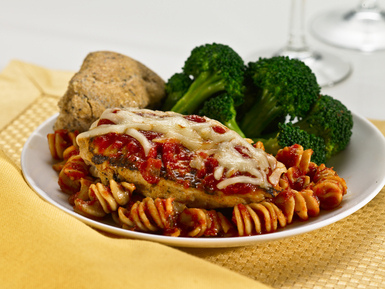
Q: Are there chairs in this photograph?
A: No, there are no chairs.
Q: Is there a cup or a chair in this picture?
A: No, there are no chairs or cups.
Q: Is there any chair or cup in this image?
A: No, there are no chairs or cups.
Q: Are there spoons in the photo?
A: No, there are no spoons.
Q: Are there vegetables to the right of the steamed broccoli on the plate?
A: Yes, there is a vegetable to the right of the broccoli.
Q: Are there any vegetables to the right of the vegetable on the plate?
A: Yes, there is a vegetable to the right of the broccoli.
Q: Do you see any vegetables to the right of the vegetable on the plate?
A: Yes, there is a vegetable to the right of the broccoli.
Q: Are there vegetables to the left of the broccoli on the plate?
A: No, the vegetable is to the right of the broccoli.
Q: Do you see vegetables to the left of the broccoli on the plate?
A: No, the vegetable is to the right of the broccoli.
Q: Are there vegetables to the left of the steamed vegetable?
A: No, the vegetable is to the right of the broccoli.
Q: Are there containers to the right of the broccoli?
A: No, there is a vegetable to the right of the broccoli.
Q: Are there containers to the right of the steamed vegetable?
A: No, there is a vegetable to the right of the broccoli.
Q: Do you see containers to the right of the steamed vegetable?
A: No, there is a vegetable to the right of the broccoli.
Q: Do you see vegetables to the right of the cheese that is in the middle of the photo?
A: Yes, there is a vegetable to the right of the cheese.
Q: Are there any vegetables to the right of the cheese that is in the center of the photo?
A: Yes, there is a vegetable to the right of the cheese.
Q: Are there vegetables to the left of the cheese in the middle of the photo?
A: No, the vegetable is to the right of the cheese.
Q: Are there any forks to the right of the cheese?
A: No, there is a vegetable to the right of the cheese.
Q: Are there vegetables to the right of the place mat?
A: Yes, there is a vegetable to the right of the place mat.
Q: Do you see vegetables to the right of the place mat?
A: Yes, there is a vegetable to the right of the place mat.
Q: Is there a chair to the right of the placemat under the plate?
A: No, there is a vegetable to the right of the placemat.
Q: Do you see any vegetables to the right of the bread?
A: Yes, there is a vegetable to the right of the bread.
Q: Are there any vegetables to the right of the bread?
A: Yes, there is a vegetable to the right of the bread.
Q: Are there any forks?
A: No, there are no forks.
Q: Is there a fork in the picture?
A: No, there are no forks.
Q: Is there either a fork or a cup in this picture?
A: No, there are no forks or cups.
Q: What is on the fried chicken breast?
A: The sauce is on the chicken breast.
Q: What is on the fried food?
A: The sauce is on the chicken breast.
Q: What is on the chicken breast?
A: The sauce is on the chicken breast.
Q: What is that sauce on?
A: The sauce is on the chicken breast.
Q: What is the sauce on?
A: The sauce is on the chicken breast.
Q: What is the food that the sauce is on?
A: The food is chicken breast.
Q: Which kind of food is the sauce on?
A: The sauce is on the chicken breast.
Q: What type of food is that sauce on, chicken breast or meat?
A: The sauce is on chicken breast.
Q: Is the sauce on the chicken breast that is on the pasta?
A: Yes, the sauce is on the chicken breast.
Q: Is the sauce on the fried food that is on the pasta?
A: Yes, the sauce is on the chicken breast.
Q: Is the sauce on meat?
A: No, the sauce is on the chicken breast.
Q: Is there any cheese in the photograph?
A: Yes, there is cheese.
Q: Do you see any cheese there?
A: Yes, there is cheese.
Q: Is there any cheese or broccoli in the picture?
A: Yes, there is cheese.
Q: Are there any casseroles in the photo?
A: No, there are no casseroles.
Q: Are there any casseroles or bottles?
A: No, there are no casseroles or bottles.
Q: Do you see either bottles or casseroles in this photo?
A: No, there are no casseroles or bottles.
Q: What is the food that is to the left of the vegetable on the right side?
A: The food is cheese.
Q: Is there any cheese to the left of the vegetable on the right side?
A: Yes, there is cheese to the left of the vegetable.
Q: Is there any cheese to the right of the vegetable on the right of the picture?
A: No, the cheese is to the left of the vegetable.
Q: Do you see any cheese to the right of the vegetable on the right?
A: No, the cheese is to the left of the vegetable.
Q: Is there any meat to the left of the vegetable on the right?
A: No, there is cheese to the left of the vegetable.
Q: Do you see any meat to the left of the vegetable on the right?
A: No, there is cheese to the left of the vegetable.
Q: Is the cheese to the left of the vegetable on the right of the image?
A: Yes, the cheese is to the left of the vegetable.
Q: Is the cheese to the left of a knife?
A: No, the cheese is to the left of the vegetable.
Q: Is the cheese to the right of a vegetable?
A: No, the cheese is to the left of a vegetable.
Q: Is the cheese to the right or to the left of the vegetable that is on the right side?
A: The cheese is to the left of the vegetable.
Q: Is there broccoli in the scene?
A: Yes, there is broccoli.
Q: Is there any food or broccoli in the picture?
A: Yes, there is broccoli.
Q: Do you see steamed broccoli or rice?
A: Yes, there is steamed broccoli.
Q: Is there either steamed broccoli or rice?
A: Yes, there is steamed broccoli.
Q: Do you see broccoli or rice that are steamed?
A: Yes, the broccoli is steamed.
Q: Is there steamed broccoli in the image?
A: Yes, there is steamed broccoli.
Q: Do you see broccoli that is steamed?
A: Yes, there is broccoli that is steamed.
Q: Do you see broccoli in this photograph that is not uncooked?
A: Yes, there is steamed broccoli.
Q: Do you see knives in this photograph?
A: No, there are no knives.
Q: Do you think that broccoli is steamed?
A: Yes, the broccoli is steamed.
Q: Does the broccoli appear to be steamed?
A: Yes, the broccoli is steamed.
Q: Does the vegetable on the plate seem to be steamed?
A: Yes, the broccoli is steamed.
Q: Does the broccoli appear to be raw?
A: No, the broccoli is steamed.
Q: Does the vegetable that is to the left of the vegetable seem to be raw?
A: No, the broccoli is steamed.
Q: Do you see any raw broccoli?
A: No, there is broccoli but it is steamed.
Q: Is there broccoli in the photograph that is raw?
A: No, there is broccoli but it is steamed.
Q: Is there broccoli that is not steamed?
A: No, there is broccoli but it is steamed.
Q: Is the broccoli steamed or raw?
A: The broccoli is steamed.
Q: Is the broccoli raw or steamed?
A: The broccoli is steamed.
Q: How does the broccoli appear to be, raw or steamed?
A: The broccoli is steamed.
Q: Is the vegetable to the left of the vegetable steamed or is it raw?
A: The broccoli is steamed.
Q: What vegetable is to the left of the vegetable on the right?
A: The vegetable is broccoli.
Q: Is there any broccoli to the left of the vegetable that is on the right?
A: Yes, there is broccoli to the left of the vegetable.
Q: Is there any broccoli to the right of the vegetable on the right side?
A: No, the broccoli is to the left of the vegetable.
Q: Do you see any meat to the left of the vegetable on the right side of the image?
A: No, there is broccoli to the left of the vegetable.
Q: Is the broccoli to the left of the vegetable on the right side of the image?
A: Yes, the broccoli is to the left of the vegetable.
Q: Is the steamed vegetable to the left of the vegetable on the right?
A: Yes, the broccoli is to the left of the vegetable.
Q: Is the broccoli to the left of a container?
A: No, the broccoli is to the left of the vegetable.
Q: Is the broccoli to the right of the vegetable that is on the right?
A: No, the broccoli is to the left of the vegetable.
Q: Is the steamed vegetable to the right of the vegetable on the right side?
A: No, the broccoli is to the left of the vegetable.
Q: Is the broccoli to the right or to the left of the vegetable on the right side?
A: The broccoli is to the left of the vegetable.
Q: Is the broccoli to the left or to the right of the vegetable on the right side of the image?
A: The broccoli is to the left of the vegetable.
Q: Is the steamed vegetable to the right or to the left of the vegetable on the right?
A: The broccoli is to the left of the vegetable.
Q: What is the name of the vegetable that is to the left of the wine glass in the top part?
A: The vegetable is broccoli.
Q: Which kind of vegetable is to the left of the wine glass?
A: The vegetable is broccoli.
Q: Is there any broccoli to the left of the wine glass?
A: Yes, there is broccoli to the left of the wine glass.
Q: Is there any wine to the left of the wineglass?
A: No, there is broccoli to the left of the wineglass.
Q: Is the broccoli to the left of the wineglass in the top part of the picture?
A: Yes, the broccoli is to the left of the wineglass.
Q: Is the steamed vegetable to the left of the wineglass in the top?
A: Yes, the broccoli is to the left of the wineglass.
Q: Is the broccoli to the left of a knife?
A: No, the broccoli is to the left of the wineglass.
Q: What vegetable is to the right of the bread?
A: The vegetable is broccoli.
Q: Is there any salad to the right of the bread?
A: No, there is broccoli to the right of the bread.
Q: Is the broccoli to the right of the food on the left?
A: Yes, the broccoli is to the right of the bread.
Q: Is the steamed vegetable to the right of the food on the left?
A: Yes, the broccoli is to the right of the bread.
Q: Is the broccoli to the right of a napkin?
A: No, the broccoli is to the right of the bread.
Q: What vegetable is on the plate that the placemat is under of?
A: The vegetable is broccoli.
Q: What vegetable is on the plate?
A: The vegetable is broccoli.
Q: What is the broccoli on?
A: The broccoli is on the plate.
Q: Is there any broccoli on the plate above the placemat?
A: Yes, there is broccoli on the plate.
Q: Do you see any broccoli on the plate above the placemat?
A: Yes, there is broccoli on the plate.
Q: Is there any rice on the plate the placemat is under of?
A: No, there is broccoli on the plate.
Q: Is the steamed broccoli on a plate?
A: Yes, the broccoli is on a plate.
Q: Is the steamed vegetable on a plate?
A: Yes, the broccoli is on a plate.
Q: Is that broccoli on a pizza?
A: No, the broccoli is on a plate.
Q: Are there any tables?
A: Yes, there is a table.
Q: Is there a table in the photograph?
A: Yes, there is a table.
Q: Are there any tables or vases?
A: Yes, there is a table.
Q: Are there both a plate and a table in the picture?
A: Yes, there are both a table and a plate.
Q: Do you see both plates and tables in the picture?
A: Yes, there are both a table and a plate.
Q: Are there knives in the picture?
A: No, there are no knives.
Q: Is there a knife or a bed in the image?
A: No, there are no knives or beds.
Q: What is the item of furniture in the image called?
A: The piece of furniture is a table.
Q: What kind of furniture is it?
A: The piece of furniture is a table.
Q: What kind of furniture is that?
A: This is a table.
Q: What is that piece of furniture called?
A: This is a table.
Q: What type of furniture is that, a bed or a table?
A: This is a table.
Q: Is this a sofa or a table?
A: This is a table.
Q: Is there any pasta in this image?
A: Yes, there is pasta.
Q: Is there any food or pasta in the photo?
A: Yes, there is pasta.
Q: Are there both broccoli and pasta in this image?
A: Yes, there are both pasta and broccoli.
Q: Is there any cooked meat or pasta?
A: Yes, there is cooked pasta.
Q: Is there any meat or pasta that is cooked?
A: Yes, the pasta is cooked.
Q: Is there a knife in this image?
A: No, there are no knives.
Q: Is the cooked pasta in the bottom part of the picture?
A: Yes, the pasta is in the bottom of the image.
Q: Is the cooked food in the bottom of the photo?
A: Yes, the pasta is in the bottom of the image.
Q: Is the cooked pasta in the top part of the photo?
A: No, the pasta is in the bottom of the image.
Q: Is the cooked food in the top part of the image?
A: No, the pasta is in the bottom of the image.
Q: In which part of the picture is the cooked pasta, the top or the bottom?
A: The pasta is in the bottom of the image.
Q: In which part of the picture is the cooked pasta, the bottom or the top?
A: The pasta is in the bottom of the image.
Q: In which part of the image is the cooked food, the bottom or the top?
A: The pasta is in the bottom of the image.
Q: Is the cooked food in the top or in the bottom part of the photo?
A: The pasta is in the bottom of the image.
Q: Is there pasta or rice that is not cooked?
A: No, there is pasta but it is cooked.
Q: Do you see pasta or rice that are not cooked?
A: No, there is pasta but it is cooked.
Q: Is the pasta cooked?
A: Yes, the pasta is cooked.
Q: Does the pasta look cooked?
A: Yes, the pasta is cooked.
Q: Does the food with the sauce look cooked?
A: Yes, the pasta is cooked.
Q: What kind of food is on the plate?
A: The food is pasta.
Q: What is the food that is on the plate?
A: The food is pasta.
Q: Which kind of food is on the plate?
A: The food is pasta.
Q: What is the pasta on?
A: The pasta is on the plate.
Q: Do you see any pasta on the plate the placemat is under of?
A: Yes, there is pasta on the plate.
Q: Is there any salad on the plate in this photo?
A: No, there is pasta on the plate.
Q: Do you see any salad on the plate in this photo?
A: No, there is pasta on the plate.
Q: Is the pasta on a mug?
A: No, the pasta is on the plate.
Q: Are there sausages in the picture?
A: No, there are no sausages.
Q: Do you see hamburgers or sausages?
A: No, there are no sausages or hamburgers.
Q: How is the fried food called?
A: The food is chicken breast.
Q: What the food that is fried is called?
A: The food is chicken breast.